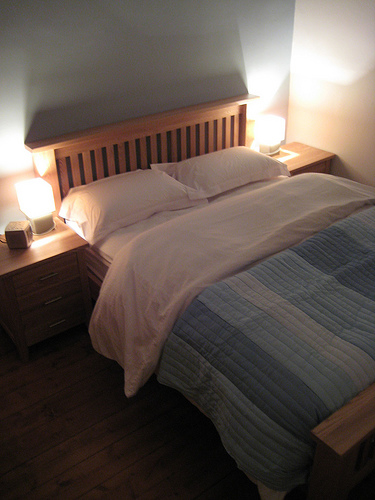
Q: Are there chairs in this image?
A: No, there are no chairs.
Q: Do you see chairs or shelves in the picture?
A: No, there are no chairs or shelves.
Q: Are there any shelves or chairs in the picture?
A: No, there are no chairs or shelves.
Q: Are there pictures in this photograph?
A: No, there are no pictures.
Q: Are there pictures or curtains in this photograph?
A: No, there are no pictures or curtains.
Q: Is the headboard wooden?
A: Yes, the headboard is wooden.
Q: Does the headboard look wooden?
A: Yes, the headboard is wooden.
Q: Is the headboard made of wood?
A: Yes, the headboard is made of wood.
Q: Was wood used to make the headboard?
A: Yes, the headboard is made of wood.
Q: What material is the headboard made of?
A: The headboard is made of wood.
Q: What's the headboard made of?
A: The headboard is made of wood.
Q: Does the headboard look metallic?
A: No, the headboard is wooden.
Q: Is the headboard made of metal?
A: No, the headboard is made of wood.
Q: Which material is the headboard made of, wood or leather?
A: The headboard is made of wood.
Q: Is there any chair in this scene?
A: No, there are no chairs.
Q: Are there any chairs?
A: No, there are no chairs.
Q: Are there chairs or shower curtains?
A: No, there are no chairs or shower curtains.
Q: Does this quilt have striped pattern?
A: Yes, the quilt is striped.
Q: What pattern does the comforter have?
A: The comforter has striped pattern.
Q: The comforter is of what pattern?
A: The comforter is striped.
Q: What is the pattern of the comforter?
A: The comforter is striped.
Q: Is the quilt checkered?
A: No, the quilt is striped.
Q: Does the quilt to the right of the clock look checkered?
A: No, the comforter is striped.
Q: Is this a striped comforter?
A: Yes, this is a striped comforter.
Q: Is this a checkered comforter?
A: No, this is a striped comforter.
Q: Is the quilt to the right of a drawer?
A: Yes, the quilt is to the right of a drawer.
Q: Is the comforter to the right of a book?
A: No, the comforter is to the right of a drawer.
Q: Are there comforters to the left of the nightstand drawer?
A: No, the comforter is to the right of the drawer.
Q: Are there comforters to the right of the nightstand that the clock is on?
A: Yes, there is a comforter to the right of the nightstand.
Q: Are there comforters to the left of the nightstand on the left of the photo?
A: No, the comforter is to the right of the nightstand.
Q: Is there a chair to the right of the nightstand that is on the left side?
A: No, there is a comforter to the right of the nightstand.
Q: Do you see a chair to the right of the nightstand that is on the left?
A: No, there is a comforter to the right of the nightstand.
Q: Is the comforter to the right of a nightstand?
A: Yes, the comforter is to the right of a nightstand.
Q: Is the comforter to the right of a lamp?
A: No, the comforter is to the right of a nightstand.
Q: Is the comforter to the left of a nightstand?
A: No, the comforter is to the right of a nightstand.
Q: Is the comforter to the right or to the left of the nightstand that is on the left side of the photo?
A: The comforter is to the right of the nightstand.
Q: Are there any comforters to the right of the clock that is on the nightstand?
A: Yes, there is a comforter to the right of the clock.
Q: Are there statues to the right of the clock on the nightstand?
A: No, there is a comforter to the right of the clock.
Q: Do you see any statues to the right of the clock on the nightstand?
A: No, there is a comforter to the right of the clock.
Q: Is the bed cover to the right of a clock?
A: Yes, the bed cover is to the right of a clock.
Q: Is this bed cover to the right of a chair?
A: No, the bed cover is to the right of a clock.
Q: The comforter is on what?
A: The comforter is on the bed.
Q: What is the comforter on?
A: The comforter is on the bed.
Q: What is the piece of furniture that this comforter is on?
A: The piece of furniture is a bed.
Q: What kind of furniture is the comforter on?
A: The comforter is on the bed.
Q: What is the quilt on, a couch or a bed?
A: The quilt is on a bed.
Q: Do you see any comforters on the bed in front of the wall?
A: Yes, there is a comforter on the bed.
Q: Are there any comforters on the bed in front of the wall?
A: Yes, there is a comforter on the bed.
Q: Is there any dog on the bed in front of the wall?
A: No, there is a comforter on the bed.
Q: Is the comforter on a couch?
A: No, the comforter is on the bed.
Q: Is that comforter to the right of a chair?
A: No, the comforter is to the right of a drawer.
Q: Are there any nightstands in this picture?
A: Yes, there is a nightstand.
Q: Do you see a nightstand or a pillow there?
A: Yes, there is a nightstand.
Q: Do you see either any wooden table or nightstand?
A: Yes, there is a wood nightstand.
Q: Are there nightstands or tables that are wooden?
A: Yes, the nightstand is wooden.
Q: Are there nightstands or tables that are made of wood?
A: Yes, the nightstand is made of wood.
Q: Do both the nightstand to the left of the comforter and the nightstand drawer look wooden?
A: Yes, both the nightstand and the drawer are wooden.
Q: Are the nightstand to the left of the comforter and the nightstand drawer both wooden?
A: Yes, both the nightstand and the drawer are wooden.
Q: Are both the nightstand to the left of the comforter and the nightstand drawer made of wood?
A: Yes, both the nightstand and the drawer are made of wood.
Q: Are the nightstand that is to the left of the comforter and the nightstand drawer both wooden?
A: Yes, both the nightstand and the drawer are wooden.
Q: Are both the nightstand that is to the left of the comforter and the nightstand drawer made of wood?
A: Yes, both the nightstand and the drawer are made of wood.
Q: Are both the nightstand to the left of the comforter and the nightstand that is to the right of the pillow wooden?
A: Yes, both the nightstand and the nightstand are wooden.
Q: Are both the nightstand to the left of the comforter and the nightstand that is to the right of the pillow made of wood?
A: Yes, both the nightstand and the nightstand are made of wood.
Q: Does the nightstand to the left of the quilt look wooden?
A: Yes, the nightstand is wooden.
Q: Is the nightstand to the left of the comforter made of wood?
A: Yes, the nightstand is made of wood.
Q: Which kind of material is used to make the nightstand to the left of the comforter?
A: The nightstand is made of wood.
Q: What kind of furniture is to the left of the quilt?
A: The piece of furniture is a nightstand.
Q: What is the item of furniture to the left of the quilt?
A: The piece of furniture is a nightstand.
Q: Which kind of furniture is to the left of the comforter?
A: The piece of furniture is a nightstand.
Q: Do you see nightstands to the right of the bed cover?
A: No, the nightstand is to the left of the bed cover.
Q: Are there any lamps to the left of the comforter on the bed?
A: No, there is a nightstand to the left of the bed cover.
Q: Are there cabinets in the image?
A: No, there are no cabinets.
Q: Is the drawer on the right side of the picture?
A: No, the drawer is on the left of the image.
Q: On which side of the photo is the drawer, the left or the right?
A: The drawer is on the left of the image.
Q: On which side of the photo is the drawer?
A: The drawer is on the left of the image.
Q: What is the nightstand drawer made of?
A: The drawer is made of wood.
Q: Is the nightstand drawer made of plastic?
A: No, the drawer is made of wood.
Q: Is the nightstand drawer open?
A: No, the drawer is closed.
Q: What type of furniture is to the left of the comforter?
A: The piece of furniture is a drawer.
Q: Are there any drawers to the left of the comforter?
A: Yes, there is a drawer to the left of the comforter.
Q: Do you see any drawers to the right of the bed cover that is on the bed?
A: No, the drawer is to the left of the comforter.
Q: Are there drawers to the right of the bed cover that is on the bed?
A: No, the drawer is to the left of the comforter.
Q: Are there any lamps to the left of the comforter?
A: No, there is a drawer to the left of the comforter.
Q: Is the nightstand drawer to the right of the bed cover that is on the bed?
A: No, the drawer is to the left of the comforter.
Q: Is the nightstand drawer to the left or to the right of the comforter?
A: The drawer is to the left of the comforter.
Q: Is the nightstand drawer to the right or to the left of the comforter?
A: The drawer is to the left of the comforter.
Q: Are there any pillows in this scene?
A: Yes, there is a pillow.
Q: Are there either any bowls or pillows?
A: Yes, there is a pillow.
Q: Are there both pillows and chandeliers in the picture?
A: No, there is a pillow but no chandeliers.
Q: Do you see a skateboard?
A: No, there are no skateboards.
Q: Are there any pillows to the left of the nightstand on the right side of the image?
A: Yes, there is a pillow to the left of the nightstand.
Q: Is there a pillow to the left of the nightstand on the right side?
A: Yes, there is a pillow to the left of the nightstand.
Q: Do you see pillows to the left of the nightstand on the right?
A: Yes, there is a pillow to the left of the nightstand.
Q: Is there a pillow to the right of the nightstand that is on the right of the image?
A: No, the pillow is to the left of the nightstand.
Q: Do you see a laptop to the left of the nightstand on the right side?
A: No, there is a pillow to the left of the nightstand.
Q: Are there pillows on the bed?
A: Yes, there is a pillow on the bed.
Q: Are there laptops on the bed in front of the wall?
A: No, there is a pillow on the bed.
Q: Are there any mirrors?
A: No, there are no mirrors.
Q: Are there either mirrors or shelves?
A: No, there are no mirrors or shelves.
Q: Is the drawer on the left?
A: Yes, the drawer is on the left of the image.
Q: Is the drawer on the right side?
A: No, the drawer is on the left of the image.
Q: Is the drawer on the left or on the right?
A: The drawer is on the left of the image.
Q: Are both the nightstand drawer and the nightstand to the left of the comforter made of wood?
A: Yes, both the drawer and the nightstand are made of wood.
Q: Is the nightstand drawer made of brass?
A: No, the drawer is made of wood.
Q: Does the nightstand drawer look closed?
A: Yes, the drawer is closed.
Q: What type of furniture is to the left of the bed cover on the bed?
A: The piece of furniture is a drawer.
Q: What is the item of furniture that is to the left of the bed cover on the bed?
A: The piece of furniture is a drawer.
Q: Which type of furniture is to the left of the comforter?
A: The piece of furniture is a drawer.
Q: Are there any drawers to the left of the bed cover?
A: Yes, there is a drawer to the left of the bed cover.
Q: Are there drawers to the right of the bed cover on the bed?
A: No, the drawer is to the left of the quilt.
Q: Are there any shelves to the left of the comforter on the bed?
A: No, there is a drawer to the left of the comforter.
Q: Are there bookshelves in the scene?
A: No, there are no bookshelves.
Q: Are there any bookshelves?
A: No, there are no bookshelves.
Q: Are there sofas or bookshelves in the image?
A: No, there are no bookshelves or sofas.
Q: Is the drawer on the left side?
A: Yes, the drawer is on the left of the image.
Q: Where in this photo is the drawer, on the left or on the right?
A: The drawer is on the left of the image.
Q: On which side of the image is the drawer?
A: The drawer is on the left of the image.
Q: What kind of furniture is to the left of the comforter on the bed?
A: The piece of furniture is a drawer.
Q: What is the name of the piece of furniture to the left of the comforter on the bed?
A: The piece of furniture is a drawer.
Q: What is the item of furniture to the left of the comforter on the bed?
A: The piece of furniture is a drawer.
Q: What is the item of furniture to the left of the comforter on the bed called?
A: The piece of furniture is a drawer.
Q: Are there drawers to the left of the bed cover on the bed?
A: Yes, there is a drawer to the left of the comforter.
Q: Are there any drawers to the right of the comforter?
A: No, the drawer is to the left of the comforter.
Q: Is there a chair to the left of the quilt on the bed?
A: No, there is a drawer to the left of the comforter.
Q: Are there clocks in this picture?
A: Yes, there is a clock.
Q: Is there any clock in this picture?
A: Yes, there is a clock.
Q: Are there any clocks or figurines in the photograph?
A: Yes, there is a clock.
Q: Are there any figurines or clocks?
A: Yes, there is a clock.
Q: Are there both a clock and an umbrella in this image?
A: No, there is a clock but no umbrellas.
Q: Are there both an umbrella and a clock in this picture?
A: No, there is a clock but no umbrellas.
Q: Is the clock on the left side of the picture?
A: Yes, the clock is on the left of the image.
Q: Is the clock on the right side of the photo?
A: No, the clock is on the left of the image.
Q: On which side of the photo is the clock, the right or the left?
A: The clock is on the left of the image.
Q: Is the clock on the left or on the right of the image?
A: The clock is on the left of the image.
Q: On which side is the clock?
A: The clock is on the left of the image.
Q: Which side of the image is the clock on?
A: The clock is on the left of the image.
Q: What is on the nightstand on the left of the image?
A: The clock is on the nightstand.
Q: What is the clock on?
A: The clock is on the nightstand.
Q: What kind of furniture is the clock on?
A: The clock is on the nightstand.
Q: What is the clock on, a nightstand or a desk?
A: The clock is on a nightstand.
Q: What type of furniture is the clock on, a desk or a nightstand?
A: The clock is on a nightstand.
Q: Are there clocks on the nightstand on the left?
A: Yes, there is a clock on the nightstand.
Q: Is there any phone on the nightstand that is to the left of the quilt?
A: No, there is a clock on the nightstand.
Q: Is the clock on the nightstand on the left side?
A: Yes, the clock is on the nightstand.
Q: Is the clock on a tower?
A: No, the clock is on the nightstand.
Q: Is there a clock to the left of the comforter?
A: Yes, there is a clock to the left of the comforter.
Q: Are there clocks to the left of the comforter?
A: Yes, there is a clock to the left of the comforter.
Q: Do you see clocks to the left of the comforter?
A: Yes, there is a clock to the left of the comforter.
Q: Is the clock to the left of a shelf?
A: No, the clock is to the left of the comforter.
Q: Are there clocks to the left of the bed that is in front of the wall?
A: Yes, there is a clock to the left of the bed.